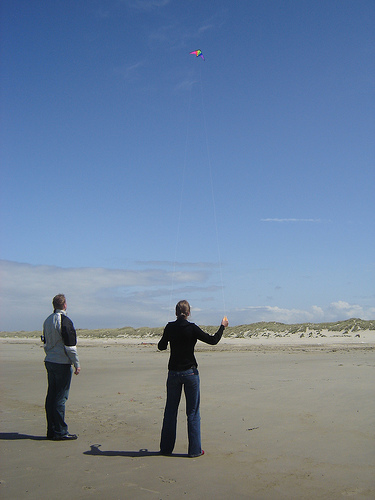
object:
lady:
[158, 300, 229, 456]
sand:
[1, 332, 375, 499]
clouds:
[0, 0, 374, 332]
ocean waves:
[41, 293, 80, 439]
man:
[40, 294, 81, 439]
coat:
[40, 308, 80, 367]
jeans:
[44, 362, 74, 438]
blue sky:
[0, 0, 375, 328]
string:
[169, 62, 226, 315]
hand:
[221, 318, 228, 326]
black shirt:
[158, 319, 226, 370]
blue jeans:
[160, 366, 200, 456]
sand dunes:
[0, 318, 375, 342]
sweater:
[157, 319, 225, 371]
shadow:
[83, 444, 188, 457]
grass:
[0, 317, 375, 337]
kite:
[189, 49, 205, 62]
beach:
[1, 337, 373, 497]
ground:
[2, 343, 373, 497]